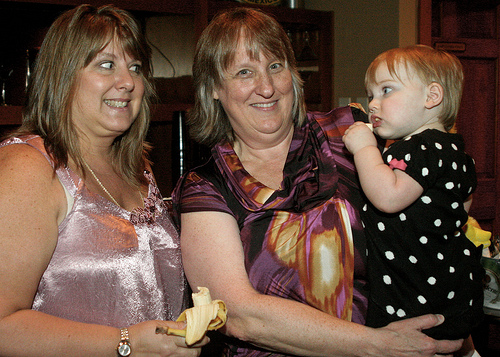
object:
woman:
[170, 7, 462, 357]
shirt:
[170, 102, 369, 357]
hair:
[364, 44, 465, 131]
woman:
[0, 4, 210, 357]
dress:
[358, 127, 483, 339]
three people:
[0, 5, 478, 357]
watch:
[115, 327, 132, 355]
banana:
[167, 286, 227, 346]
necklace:
[79, 153, 145, 207]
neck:
[65, 124, 116, 154]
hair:
[187, 8, 304, 143]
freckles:
[265, 308, 317, 337]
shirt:
[0, 134, 186, 329]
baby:
[342, 44, 485, 340]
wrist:
[108, 326, 132, 356]